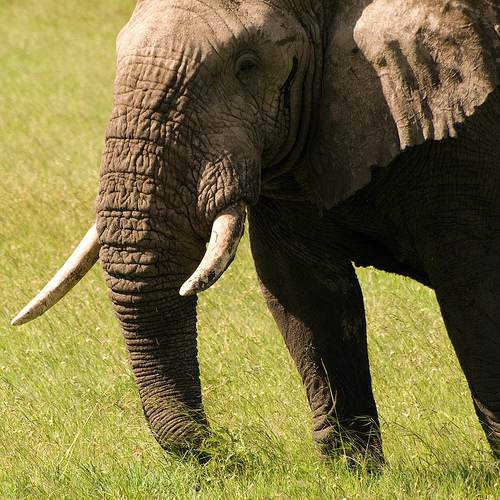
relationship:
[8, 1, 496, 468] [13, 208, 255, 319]
elephant has ivory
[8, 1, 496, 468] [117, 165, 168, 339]
elephant has wrinkles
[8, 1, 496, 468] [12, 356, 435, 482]
elephant on field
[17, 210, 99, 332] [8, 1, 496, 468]
tusk of elephant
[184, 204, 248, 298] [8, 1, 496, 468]
tusk of elephant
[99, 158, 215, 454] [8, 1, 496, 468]
trunk of elephant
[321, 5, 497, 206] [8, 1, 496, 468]
ear of elephant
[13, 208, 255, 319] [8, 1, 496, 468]
tusks of elephant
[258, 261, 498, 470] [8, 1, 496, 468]
legs of elephant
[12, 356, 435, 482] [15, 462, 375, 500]
field with grass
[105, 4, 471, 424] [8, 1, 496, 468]
front of elephant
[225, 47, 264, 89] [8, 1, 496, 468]
eye of elephant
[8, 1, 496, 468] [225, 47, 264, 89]
elephant left eye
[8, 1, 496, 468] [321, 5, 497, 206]
elephant left ear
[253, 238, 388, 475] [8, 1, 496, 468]
legs of elephant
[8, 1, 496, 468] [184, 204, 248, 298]
elephant has horn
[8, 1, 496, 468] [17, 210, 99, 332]
elephant has horn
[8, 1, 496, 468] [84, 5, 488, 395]
elephant at rest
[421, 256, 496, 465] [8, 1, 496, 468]
arm of elephant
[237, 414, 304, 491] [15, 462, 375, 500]
patch of grass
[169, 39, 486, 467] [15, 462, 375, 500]
standing in grass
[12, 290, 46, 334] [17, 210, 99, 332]
tip of tusk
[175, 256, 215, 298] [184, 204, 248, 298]
tip of tusk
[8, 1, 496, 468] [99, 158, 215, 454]
elephant has trunk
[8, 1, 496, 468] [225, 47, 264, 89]
elephant's small eye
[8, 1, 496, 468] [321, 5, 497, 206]
elephant's big ear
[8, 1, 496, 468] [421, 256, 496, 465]
elephant's left leg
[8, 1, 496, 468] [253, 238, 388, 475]
elephant's right legs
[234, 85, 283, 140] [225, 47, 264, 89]
wrinkles beside eye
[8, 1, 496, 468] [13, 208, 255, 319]
elephant has tusks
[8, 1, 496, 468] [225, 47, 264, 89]
elephant has eye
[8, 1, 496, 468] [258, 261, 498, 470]
elephant has legs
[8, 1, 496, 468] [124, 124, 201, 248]
elephant has skin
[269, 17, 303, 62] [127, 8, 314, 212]
mud on face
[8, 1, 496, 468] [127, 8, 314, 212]
elephant has face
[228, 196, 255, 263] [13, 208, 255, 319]
mud on tusks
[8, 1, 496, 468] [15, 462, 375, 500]
elephant in grass